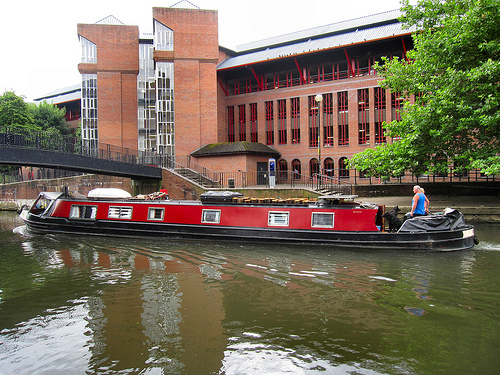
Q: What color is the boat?
A: Red.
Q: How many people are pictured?
A: One.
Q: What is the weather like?
A: Overcast.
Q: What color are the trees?
A: Green.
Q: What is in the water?
A: A boat.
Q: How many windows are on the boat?
A: 6.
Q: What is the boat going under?
A: A bridge.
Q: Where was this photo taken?
A: On the river walk.